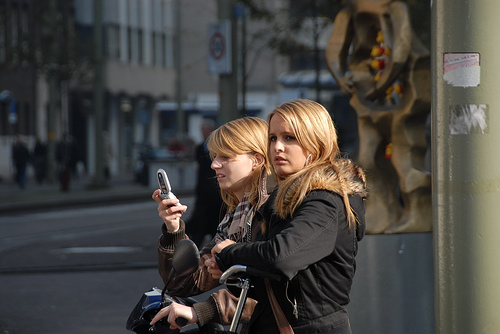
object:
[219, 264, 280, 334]
bar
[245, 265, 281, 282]
handle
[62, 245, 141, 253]
manhole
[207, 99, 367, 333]
ladies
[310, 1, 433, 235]
sculpture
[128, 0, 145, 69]
window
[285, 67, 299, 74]
leaves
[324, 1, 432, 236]
figure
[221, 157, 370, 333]
coat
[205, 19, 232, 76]
sign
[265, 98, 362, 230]
hair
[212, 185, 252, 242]
scarf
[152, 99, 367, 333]
girl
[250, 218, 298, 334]
strap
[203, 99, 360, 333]
body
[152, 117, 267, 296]
woman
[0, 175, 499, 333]
street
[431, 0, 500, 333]
post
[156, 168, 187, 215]
cell phone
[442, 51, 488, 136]
sticker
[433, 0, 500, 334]
pole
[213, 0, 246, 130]
post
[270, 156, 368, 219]
fur lining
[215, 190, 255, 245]
fabric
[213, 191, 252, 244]
shirt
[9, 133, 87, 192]
people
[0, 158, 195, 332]
sidewalk